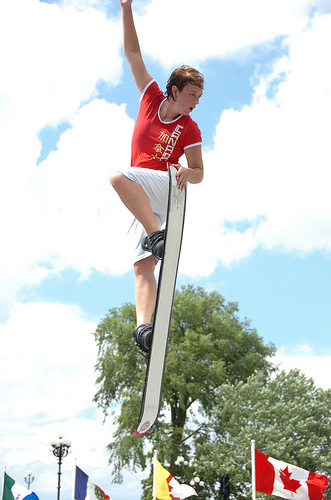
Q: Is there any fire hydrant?
A: No, there are no fire hydrants.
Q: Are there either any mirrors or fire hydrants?
A: No, there are no fire hydrants or mirrors.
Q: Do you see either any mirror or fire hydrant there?
A: No, there are no fire hydrants or mirrors.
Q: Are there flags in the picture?
A: Yes, there is a flag.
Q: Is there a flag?
A: Yes, there is a flag.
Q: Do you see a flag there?
A: Yes, there is a flag.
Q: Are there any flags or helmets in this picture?
A: Yes, there is a flag.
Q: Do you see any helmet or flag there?
A: Yes, there is a flag.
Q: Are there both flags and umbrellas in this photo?
A: No, there is a flag but no umbrellas.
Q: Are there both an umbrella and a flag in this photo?
A: No, there is a flag but no umbrellas.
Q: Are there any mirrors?
A: No, there are no mirrors.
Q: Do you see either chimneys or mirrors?
A: No, there are no mirrors or chimneys.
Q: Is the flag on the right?
A: Yes, the flag is on the right of the image.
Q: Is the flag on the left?
A: No, the flag is on the right of the image.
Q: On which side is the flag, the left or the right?
A: The flag is on the right of the image.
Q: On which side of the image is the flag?
A: The flag is on the right of the image.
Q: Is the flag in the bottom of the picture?
A: Yes, the flag is in the bottom of the image.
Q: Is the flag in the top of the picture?
A: No, the flag is in the bottom of the image.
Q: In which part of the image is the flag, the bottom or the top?
A: The flag is in the bottom of the image.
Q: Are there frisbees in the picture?
A: No, there are no frisbees.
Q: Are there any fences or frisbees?
A: No, there are no frisbees or fences.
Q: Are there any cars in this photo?
A: No, there are no cars.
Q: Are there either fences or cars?
A: No, there are no cars or fences.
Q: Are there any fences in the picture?
A: No, there are no fences.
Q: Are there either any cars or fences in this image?
A: No, there are no fences or cars.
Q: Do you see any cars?
A: No, there are no cars.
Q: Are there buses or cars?
A: No, there are no cars or buses.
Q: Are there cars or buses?
A: No, there are no cars or buses.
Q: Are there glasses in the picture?
A: No, there are no glasses.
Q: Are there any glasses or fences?
A: No, there are no glasses or fences.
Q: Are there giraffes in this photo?
A: No, there are no giraffes.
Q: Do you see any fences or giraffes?
A: No, there are no giraffes or fences.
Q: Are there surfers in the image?
A: No, there are no surfers.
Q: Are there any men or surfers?
A: No, there are no surfers or men.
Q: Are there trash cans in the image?
A: No, there are no trash cans.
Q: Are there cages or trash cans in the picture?
A: No, there are no trash cans or cages.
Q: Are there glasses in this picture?
A: No, there are no glasses.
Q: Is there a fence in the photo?
A: No, there are no fences.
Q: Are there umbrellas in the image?
A: No, there are no umbrellas.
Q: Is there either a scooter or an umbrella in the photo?
A: No, there are no umbrellas or scooters.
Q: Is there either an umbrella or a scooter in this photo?
A: No, there are no umbrellas or scooters.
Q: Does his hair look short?
A: Yes, the hair is short.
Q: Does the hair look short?
A: Yes, the hair is short.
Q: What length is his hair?
A: The hair is short.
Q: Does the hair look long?
A: No, the hair is short.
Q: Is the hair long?
A: No, the hair is short.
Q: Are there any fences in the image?
A: No, there are no fences.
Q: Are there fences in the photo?
A: No, there are no fences.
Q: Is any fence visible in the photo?
A: No, there are no fences.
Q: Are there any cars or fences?
A: No, there are no fences or cars.